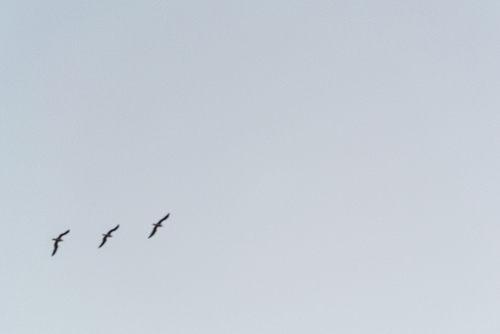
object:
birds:
[50, 228, 72, 256]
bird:
[148, 212, 170, 238]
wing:
[158, 212, 170, 222]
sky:
[253, 0, 499, 330]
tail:
[151, 221, 157, 228]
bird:
[97, 224, 120, 249]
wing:
[107, 224, 121, 234]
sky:
[0, 112, 136, 202]